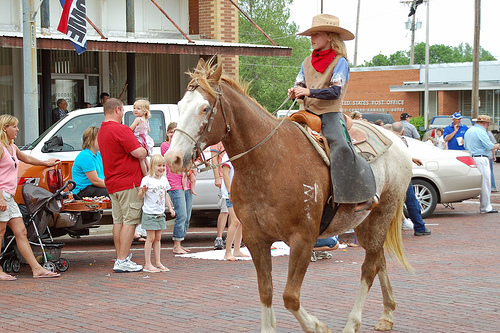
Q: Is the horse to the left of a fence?
A: No, the horse is to the left of a man.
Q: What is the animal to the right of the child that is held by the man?
A: The animal is a horse.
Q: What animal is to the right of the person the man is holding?
A: The animal is a horse.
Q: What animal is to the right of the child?
A: The animal is a horse.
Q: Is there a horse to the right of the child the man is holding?
A: Yes, there is a horse to the right of the kid.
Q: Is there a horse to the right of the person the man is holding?
A: Yes, there is a horse to the right of the kid.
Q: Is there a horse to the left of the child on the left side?
A: No, the horse is to the right of the child.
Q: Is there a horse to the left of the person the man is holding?
A: No, the horse is to the right of the child.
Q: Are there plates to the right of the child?
A: No, there is a horse to the right of the child.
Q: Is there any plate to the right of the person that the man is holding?
A: No, there is a horse to the right of the child.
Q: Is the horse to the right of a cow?
A: No, the horse is to the right of the kid.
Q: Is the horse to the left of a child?
A: No, the horse is to the right of a child.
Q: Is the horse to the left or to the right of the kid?
A: The horse is to the right of the kid.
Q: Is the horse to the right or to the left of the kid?
A: The horse is to the right of the kid.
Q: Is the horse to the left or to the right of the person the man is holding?
A: The horse is to the right of the kid.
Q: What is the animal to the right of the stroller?
A: The animal is a horse.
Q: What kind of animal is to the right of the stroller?
A: The animal is a horse.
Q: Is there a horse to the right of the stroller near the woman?
A: Yes, there is a horse to the right of the stroller.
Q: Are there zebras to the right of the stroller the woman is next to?
A: No, there is a horse to the right of the stroller.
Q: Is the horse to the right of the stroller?
A: Yes, the horse is to the right of the stroller.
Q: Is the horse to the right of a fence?
A: No, the horse is to the right of the stroller.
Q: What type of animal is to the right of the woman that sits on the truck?
A: The animal is a horse.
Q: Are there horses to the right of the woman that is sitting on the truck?
A: Yes, there is a horse to the right of the woman.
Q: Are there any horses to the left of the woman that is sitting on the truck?
A: No, the horse is to the right of the woman.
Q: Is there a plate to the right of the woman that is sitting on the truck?
A: No, there is a horse to the right of the woman.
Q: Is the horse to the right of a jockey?
A: No, the horse is to the right of the woman.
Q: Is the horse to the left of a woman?
A: No, the horse is to the right of a woman.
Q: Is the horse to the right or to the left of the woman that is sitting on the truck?
A: The horse is to the right of the woman.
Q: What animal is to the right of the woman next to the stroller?
A: The animal is a horse.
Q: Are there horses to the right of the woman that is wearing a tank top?
A: Yes, there is a horse to the right of the woman.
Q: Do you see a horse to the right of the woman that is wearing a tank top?
A: Yes, there is a horse to the right of the woman.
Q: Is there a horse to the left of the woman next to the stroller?
A: No, the horse is to the right of the woman.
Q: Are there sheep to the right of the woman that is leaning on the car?
A: No, there is a horse to the right of the woman.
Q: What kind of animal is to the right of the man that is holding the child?
A: The animal is a horse.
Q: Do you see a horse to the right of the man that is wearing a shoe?
A: Yes, there is a horse to the right of the man.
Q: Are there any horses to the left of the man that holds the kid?
A: No, the horse is to the right of the man.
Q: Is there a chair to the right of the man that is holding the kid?
A: No, there is a horse to the right of the man.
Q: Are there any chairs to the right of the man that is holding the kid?
A: No, there is a horse to the right of the man.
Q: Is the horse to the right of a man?
A: Yes, the horse is to the right of a man.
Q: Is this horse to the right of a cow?
A: No, the horse is to the right of a man.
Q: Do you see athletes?
A: No, there are no athletes.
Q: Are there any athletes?
A: No, there are no athletes.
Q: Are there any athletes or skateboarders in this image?
A: No, there are no athletes or skateboarders.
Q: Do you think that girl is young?
A: Yes, the girl is young.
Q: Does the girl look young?
A: Yes, the girl is young.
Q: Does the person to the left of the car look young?
A: Yes, the girl is young.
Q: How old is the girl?
A: The girl is young.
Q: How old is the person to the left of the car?
A: The girl is young.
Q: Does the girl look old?
A: No, the girl is young.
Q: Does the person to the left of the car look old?
A: No, the girl is young.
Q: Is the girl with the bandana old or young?
A: The girl is young.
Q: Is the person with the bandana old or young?
A: The girl is young.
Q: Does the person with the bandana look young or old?
A: The girl is young.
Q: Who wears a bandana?
A: The girl wears a bandana.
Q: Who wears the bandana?
A: The girl wears a bandana.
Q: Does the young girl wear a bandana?
A: Yes, the girl wears a bandana.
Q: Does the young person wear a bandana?
A: Yes, the girl wears a bandana.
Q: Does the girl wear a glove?
A: No, the girl wears a bandana.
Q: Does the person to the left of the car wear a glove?
A: No, the girl wears a bandana.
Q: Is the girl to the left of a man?
A: Yes, the girl is to the left of a man.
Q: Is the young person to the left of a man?
A: Yes, the girl is to the left of a man.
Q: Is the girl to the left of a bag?
A: No, the girl is to the left of a man.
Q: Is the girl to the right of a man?
A: No, the girl is to the left of a man.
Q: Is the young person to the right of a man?
A: No, the girl is to the left of a man.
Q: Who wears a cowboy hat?
A: The girl wears a cowboy hat.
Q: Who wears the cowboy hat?
A: The girl wears a cowboy hat.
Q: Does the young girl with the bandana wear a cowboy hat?
A: Yes, the girl wears a cowboy hat.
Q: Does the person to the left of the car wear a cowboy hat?
A: Yes, the girl wears a cowboy hat.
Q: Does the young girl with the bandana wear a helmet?
A: No, the girl wears a cowboy hat.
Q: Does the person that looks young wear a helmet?
A: No, the girl wears a cowboy hat.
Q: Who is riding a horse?
A: The girl is riding a horse.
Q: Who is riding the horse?
A: The girl is riding a horse.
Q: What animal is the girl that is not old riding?
A: The girl is riding a horse.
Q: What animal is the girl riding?
A: The girl is riding a horse.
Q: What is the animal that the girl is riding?
A: The animal is a horse.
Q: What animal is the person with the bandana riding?
A: The girl is riding a horse.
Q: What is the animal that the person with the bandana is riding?
A: The animal is a horse.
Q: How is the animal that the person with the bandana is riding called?
A: The animal is a horse.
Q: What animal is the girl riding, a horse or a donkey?
A: The girl is riding a horse.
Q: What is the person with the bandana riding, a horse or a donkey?
A: The girl is riding a horse.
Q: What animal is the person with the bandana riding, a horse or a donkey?
A: The girl is riding a horse.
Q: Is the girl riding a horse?
A: Yes, the girl is riding a horse.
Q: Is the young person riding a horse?
A: Yes, the girl is riding a horse.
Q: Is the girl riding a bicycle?
A: No, the girl is riding a horse.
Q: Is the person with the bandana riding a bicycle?
A: No, the girl is riding a horse.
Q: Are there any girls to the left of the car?
A: Yes, there is a girl to the left of the car.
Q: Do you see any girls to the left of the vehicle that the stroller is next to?
A: Yes, there is a girl to the left of the car.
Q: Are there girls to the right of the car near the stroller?
A: No, the girl is to the left of the car.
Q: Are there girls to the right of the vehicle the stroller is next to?
A: No, the girl is to the left of the car.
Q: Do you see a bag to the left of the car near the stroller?
A: No, there is a girl to the left of the car.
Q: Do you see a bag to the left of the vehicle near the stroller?
A: No, there is a girl to the left of the car.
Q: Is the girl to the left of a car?
A: Yes, the girl is to the left of a car.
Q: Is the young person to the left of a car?
A: Yes, the girl is to the left of a car.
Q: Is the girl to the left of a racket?
A: No, the girl is to the left of a car.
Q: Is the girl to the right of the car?
A: No, the girl is to the left of the car.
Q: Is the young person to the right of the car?
A: No, the girl is to the left of the car.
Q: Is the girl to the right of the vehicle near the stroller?
A: No, the girl is to the left of the car.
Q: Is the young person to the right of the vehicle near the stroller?
A: No, the girl is to the left of the car.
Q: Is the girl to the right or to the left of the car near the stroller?
A: The girl is to the left of the car.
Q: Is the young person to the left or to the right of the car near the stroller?
A: The girl is to the left of the car.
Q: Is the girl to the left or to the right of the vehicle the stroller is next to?
A: The girl is to the left of the car.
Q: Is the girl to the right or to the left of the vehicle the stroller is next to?
A: The girl is to the left of the car.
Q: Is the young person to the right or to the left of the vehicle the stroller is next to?
A: The girl is to the left of the car.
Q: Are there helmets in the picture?
A: No, there are no helmets.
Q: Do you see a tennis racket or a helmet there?
A: No, there are no helmets or rackets.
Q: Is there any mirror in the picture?
A: No, there are no mirrors.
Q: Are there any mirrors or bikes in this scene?
A: No, there are no mirrors or bikes.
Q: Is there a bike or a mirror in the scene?
A: No, there are no mirrors or bikes.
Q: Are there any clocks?
A: No, there are no clocks.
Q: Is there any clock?
A: No, there are no clocks.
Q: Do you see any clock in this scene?
A: No, there are no clocks.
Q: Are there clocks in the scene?
A: No, there are no clocks.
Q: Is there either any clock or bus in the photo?
A: No, there are no clocks or buses.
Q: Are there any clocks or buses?
A: No, there are no clocks or buses.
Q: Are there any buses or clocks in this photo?
A: No, there are no clocks or buses.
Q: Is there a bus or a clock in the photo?
A: No, there are no clocks or buses.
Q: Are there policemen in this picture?
A: No, there are no policemen.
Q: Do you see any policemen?
A: No, there are no policemen.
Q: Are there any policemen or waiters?
A: No, there are no policemen or waiters.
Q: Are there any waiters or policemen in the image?
A: No, there are no policemen or waiters.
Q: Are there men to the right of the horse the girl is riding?
A: Yes, there is a man to the right of the horse.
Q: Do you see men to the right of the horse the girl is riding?
A: Yes, there is a man to the right of the horse.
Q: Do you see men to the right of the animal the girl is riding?
A: Yes, there is a man to the right of the horse.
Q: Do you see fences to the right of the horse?
A: No, there is a man to the right of the horse.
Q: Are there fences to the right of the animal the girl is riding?
A: No, there is a man to the right of the horse.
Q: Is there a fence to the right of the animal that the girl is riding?
A: No, there is a man to the right of the horse.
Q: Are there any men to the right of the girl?
A: Yes, there is a man to the right of the girl.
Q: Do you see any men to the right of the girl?
A: Yes, there is a man to the right of the girl.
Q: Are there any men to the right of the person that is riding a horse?
A: Yes, there is a man to the right of the girl.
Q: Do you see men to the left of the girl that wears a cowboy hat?
A: No, the man is to the right of the girl.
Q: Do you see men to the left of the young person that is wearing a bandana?
A: No, the man is to the right of the girl.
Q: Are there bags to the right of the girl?
A: No, there is a man to the right of the girl.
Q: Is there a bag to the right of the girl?
A: No, there is a man to the right of the girl.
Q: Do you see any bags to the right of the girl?
A: No, there is a man to the right of the girl.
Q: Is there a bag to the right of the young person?
A: No, there is a man to the right of the girl.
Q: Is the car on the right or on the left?
A: The car is on the right of the image.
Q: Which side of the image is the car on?
A: The car is on the right of the image.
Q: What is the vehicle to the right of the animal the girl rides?
A: The vehicle is a car.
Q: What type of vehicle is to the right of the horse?
A: The vehicle is a car.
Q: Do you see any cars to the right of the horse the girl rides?
A: Yes, there is a car to the right of the horse.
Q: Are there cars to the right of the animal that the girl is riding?
A: Yes, there is a car to the right of the horse.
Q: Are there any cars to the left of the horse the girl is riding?
A: No, the car is to the right of the horse.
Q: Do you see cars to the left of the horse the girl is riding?
A: No, the car is to the right of the horse.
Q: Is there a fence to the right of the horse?
A: No, there is a car to the right of the horse.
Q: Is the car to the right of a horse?
A: Yes, the car is to the right of a horse.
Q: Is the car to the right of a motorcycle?
A: No, the car is to the right of a horse.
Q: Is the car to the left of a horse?
A: No, the car is to the right of a horse.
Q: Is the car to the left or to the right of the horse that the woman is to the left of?
A: The car is to the right of the horse.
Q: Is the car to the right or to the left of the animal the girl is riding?
A: The car is to the right of the horse.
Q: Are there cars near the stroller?
A: Yes, there is a car near the stroller.